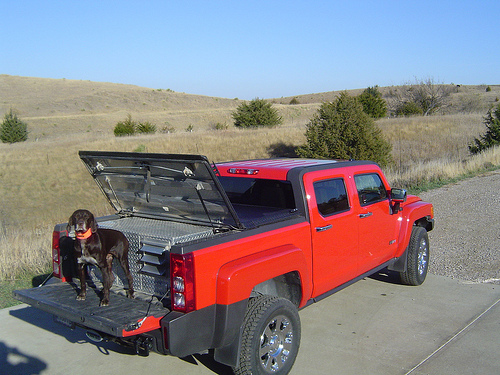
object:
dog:
[67, 213, 136, 298]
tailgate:
[13, 280, 169, 341]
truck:
[23, 152, 435, 373]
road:
[365, 174, 483, 374]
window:
[229, 174, 293, 209]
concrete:
[323, 289, 479, 364]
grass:
[403, 128, 456, 169]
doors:
[312, 166, 357, 291]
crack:
[403, 295, 495, 369]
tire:
[242, 294, 300, 374]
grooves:
[253, 300, 273, 311]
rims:
[260, 315, 295, 371]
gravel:
[444, 199, 484, 248]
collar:
[71, 229, 96, 240]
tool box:
[103, 218, 210, 300]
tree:
[309, 94, 388, 161]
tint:
[230, 181, 264, 194]